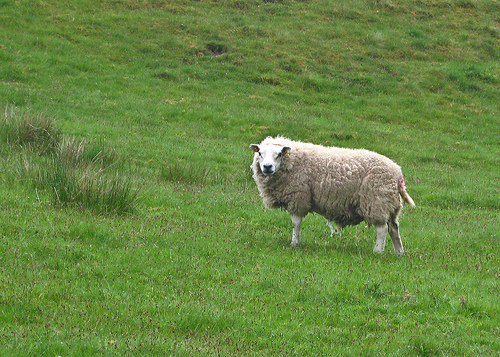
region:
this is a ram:
[251, 121, 408, 248]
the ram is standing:
[246, 138, 409, 250]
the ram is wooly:
[252, 130, 419, 247]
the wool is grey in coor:
[317, 165, 354, 201]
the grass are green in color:
[170, 242, 305, 354]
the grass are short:
[260, 269, 366, 355]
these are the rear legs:
[370, 218, 399, 253]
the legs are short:
[366, 221, 403, 253]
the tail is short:
[396, 180, 416, 204]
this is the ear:
[281, 145, 295, 155]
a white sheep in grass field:
[245, 120, 430, 271]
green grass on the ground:
[69, 239, 311, 355]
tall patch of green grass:
[9, 107, 135, 227]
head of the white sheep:
[253, 138, 288, 177]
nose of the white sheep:
[262, 162, 272, 172]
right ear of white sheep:
[249, 142, 261, 153]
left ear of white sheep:
[274, 143, 289, 158]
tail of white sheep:
[394, 173, 421, 210]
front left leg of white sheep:
[288, 210, 302, 247]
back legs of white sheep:
[368, 213, 412, 255]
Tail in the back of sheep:
[398, 174, 419, 214]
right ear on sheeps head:
[280, 141, 290, 163]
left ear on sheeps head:
[248, 143, 260, 155]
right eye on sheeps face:
[273, 150, 280, 162]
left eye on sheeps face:
[253, 149, 260, 166]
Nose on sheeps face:
[263, 162, 275, 173]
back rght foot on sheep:
[370, 218, 387, 255]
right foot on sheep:
[387, 208, 401, 258]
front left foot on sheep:
[285, 220, 306, 257]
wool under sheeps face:
[253, 174, 301, 204]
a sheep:
[244, 130, 424, 257]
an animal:
[246, 130, 426, 261]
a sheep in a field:
[76, 58, 472, 321]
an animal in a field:
[168, 74, 464, 283]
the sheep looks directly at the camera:
[247, 121, 431, 261]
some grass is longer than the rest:
[7, 94, 226, 228]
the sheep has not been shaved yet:
[242, 108, 426, 263]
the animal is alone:
[238, 122, 427, 264]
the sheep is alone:
[246, 128, 419, 265]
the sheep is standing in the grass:
[240, 109, 439, 266]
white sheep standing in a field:
[251, 135, 411, 255]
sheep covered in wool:
[249, 133, 414, 248]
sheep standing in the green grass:
[249, 133, 419, 252]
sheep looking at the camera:
[248, 134, 412, 249]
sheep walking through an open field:
[247, 135, 412, 251]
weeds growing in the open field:
[0, 105, 234, 217]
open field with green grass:
[0, 0, 498, 354]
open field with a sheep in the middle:
[0, 0, 498, 355]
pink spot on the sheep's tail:
[395, 174, 407, 189]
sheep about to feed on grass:
[250, 135, 415, 254]